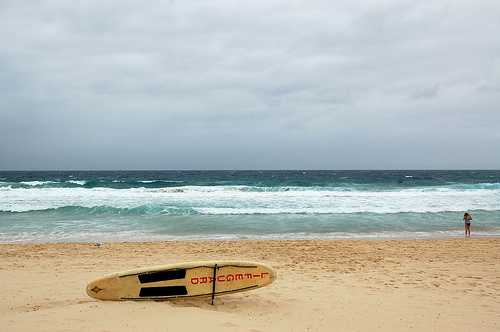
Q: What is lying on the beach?
A: A surfboard.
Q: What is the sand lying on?
A: The beach.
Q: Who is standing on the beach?
A: A woman.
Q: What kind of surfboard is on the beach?
A: A lifeguard surfboard.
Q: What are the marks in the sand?
A: Footprints.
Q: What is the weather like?
A: Dark and rainy.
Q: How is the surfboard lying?
A: On its side.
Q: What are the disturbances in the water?
A: Waves.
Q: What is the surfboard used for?
A: A flotation device.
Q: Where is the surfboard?
A: On the beach.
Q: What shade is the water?
A: Blue.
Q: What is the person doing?
A: Standing.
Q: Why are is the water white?
A: Crashing waves.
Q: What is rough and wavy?
A: The surf.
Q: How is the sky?
A: Grey and cloudy.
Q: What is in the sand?
A: A lifeguard surfboard.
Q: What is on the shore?
A: Brown sand.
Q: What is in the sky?
A: Gray clouds.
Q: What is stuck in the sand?
A: Wood colored surfboard.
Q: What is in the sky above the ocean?
A: Clouds.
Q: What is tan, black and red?
A: The surfboard.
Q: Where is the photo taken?
A: Beach.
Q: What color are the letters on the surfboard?
A: Red.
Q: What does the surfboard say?
A: Lifeguard.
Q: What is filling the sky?
A: Clouds.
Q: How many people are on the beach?
A: One.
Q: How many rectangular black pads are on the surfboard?
A: Two.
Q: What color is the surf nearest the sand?
A: Green.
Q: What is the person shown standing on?
A: Sand.